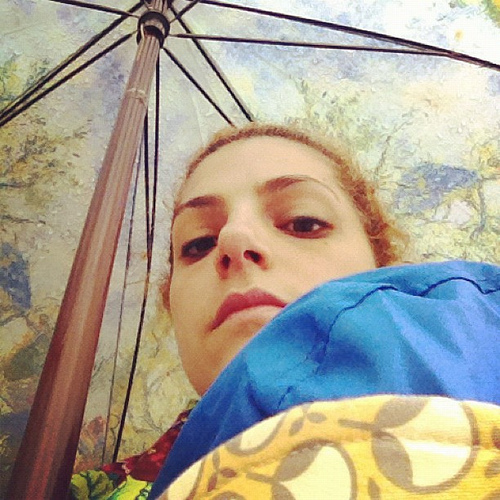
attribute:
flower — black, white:
[336, 388, 486, 498]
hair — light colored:
[178, 118, 416, 272]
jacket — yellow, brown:
[151, 391, 498, 496]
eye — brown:
[271, 209, 333, 236]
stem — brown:
[3, 1, 333, 121]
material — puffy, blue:
[145, 250, 498, 499]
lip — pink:
[206, 283, 294, 332]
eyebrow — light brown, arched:
[253, 172, 342, 202]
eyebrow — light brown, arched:
[170, 193, 221, 228]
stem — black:
[167, 2, 499, 69]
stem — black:
[160, 1, 257, 126]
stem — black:
[112, 41, 158, 458]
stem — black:
[1, 0, 145, 125]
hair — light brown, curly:
[160, 121, 411, 308]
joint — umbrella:
[136, 0, 171, 42]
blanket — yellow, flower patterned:
[155, 394, 499, 498]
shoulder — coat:
[311, 262, 498, 365]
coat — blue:
[145, 260, 498, 499]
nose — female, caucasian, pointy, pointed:
[215, 206, 271, 278]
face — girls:
[170, 133, 378, 397]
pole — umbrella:
[0, 0, 168, 497]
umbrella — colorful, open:
[1, 0, 498, 497]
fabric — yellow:
[181, 398, 497, 495]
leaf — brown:
[347, 404, 473, 486]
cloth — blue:
[187, 261, 499, 406]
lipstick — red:
[228, 292, 268, 308]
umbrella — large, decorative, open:
[5, 4, 494, 298]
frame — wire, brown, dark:
[162, 2, 335, 114]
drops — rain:
[32, 171, 87, 251]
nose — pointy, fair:
[212, 215, 270, 276]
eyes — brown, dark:
[173, 180, 347, 267]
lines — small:
[283, 228, 342, 253]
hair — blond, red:
[190, 115, 404, 253]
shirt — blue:
[205, 267, 484, 399]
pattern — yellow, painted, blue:
[338, 401, 482, 491]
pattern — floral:
[1, 174, 75, 380]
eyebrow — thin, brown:
[260, 169, 340, 198]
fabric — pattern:
[275, 269, 440, 489]